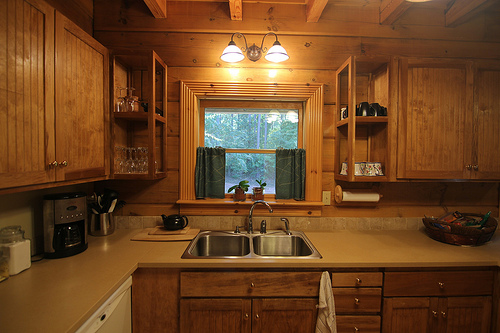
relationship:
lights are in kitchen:
[221, 30, 288, 67] [2, 2, 500, 332]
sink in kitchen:
[182, 201, 321, 259] [2, 2, 500, 332]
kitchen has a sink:
[2, 2, 500, 332] [182, 201, 321, 259]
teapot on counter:
[160, 211, 189, 230] [2, 217, 500, 332]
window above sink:
[197, 98, 309, 203] [182, 201, 321, 259]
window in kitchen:
[197, 98, 309, 203] [2, 2, 500, 332]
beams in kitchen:
[142, 1, 490, 26] [2, 2, 500, 332]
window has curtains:
[197, 98, 309, 203] [194, 147, 305, 199]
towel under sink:
[316, 270, 336, 331] [182, 201, 321, 259]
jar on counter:
[2, 223, 32, 278] [2, 217, 500, 332]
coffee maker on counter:
[35, 191, 89, 258] [2, 217, 500, 332]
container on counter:
[89, 207, 114, 235] [2, 217, 500, 332]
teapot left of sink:
[160, 211, 189, 230] [182, 201, 321, 259]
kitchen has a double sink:
[2, 2, 500, 332] [182, 201, 321, 259]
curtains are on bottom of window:
[194, 147, 305, 199] [197, 98, 309, 203]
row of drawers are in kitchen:
[328, 268, 383, 332] [2, 2, 500, 332]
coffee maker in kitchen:
[35, 191, 89, 258] [2, 2, 500, 332]